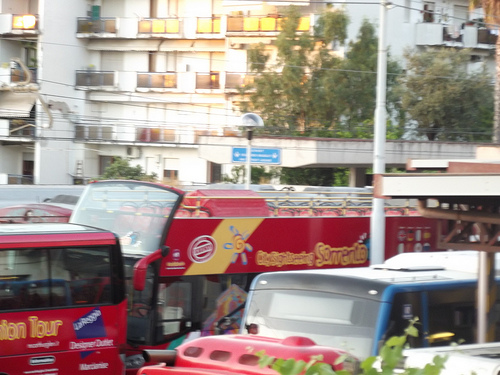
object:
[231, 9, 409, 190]
green tree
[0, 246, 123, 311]
window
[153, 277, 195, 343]
window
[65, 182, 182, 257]
window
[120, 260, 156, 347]
window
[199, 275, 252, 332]
window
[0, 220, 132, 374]
bus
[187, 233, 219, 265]
logo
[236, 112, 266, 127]
light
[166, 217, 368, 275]
paint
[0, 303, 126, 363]
paint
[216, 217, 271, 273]
stripe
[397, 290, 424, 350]
window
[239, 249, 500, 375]
bus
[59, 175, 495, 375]
bus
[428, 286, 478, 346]
window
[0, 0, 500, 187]
building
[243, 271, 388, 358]
window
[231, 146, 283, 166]
street sign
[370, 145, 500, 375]
bus stop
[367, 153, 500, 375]
area